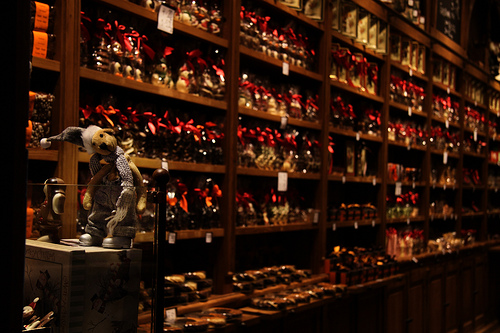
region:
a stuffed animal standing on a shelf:
[36, 115, 141, 250]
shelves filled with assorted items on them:
[32, 0, 498, 312]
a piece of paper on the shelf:
[275, 167, 291, 187]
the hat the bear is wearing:
[43, 121, 98, 151]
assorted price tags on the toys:
[238, 119, 320, 151]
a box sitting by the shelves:
[22, 239, 137, 329]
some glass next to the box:
[19, 179, 160, 331]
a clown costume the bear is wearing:
[79, 159, 140, 248]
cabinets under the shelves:
[373, 247, 494, 332]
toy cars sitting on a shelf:
[225, 256, 346, 318]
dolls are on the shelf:
[99, 3, 430, 288]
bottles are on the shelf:
[178, 263, 430, 303]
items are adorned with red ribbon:
[142, 100, 273, 160]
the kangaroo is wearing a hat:
[46, 118, 146, 226]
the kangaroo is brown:
[50, 112, 117, 207]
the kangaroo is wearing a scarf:
[79, 158, 168, 265]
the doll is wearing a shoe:
[64, 209, 214, 281]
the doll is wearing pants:
[66, 185, 176, 250]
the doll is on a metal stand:
[39, 209, 113, 301]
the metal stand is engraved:
[33, 240, 112, 298]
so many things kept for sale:
[178, 63, 474, 244]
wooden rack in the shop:
[96, 4, 430, 209]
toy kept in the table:
[51, 118, 147, 275]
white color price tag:
[271, 166, 291, 190]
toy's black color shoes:
[68, 230, 134, 250]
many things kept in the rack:
[349, 23, 472, 223]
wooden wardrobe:
[387, 274, 466, 324]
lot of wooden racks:
[347, 28, 453, 238]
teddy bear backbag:
[90, 155, 141, 221]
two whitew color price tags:
[21, 0, 52, 55]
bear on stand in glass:
[43, 111, 136, 238]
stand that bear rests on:
[26, 237, 141, 318]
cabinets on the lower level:
[386, 268, 488, 326]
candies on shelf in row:
[242, 68, 317, 110]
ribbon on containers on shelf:
[238, 128, 318, 144]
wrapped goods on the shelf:
[229, 258, 320, 283]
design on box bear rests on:
[83, 261, 138, 311]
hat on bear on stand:
[41, 120, 93, 152]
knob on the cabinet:
[406, 313, 416, 326]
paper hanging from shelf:
[157, 5, 181, 34]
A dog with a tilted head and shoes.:
[38, 125, 142, 250]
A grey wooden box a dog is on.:
[24, 235, 143, 331]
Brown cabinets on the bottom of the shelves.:
[374, 255, 499, 332]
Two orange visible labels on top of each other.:
[30, 0, 46, 58]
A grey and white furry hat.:
[39, 122, 102, 156]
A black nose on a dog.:
[98, 140, 109, 150]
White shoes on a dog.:
[78, 232, 132, 249]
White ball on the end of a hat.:
[39, 136, 52, 148]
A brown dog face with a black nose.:
[87, 127, 119, 156]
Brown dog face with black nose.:
[85, 126, 121, 156]